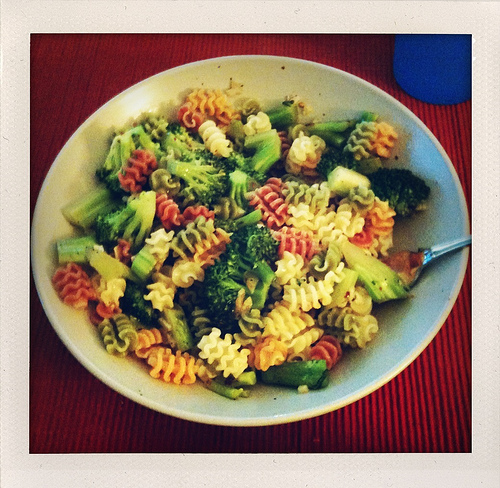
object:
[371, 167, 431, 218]
broccoli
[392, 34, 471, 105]
blue cup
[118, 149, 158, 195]
peice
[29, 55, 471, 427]
peice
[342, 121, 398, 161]
piece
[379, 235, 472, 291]
fork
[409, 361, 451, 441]
motorcycles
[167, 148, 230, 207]
broccoli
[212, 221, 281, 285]
broccoli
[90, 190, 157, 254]
broccoli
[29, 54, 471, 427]
bowl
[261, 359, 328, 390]
broccoli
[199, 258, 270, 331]
broccoli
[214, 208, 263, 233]
broccoli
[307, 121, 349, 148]
broccoli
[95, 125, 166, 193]
broccoli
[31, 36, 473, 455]
table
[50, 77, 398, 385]
noodles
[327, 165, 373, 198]
piece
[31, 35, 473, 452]
placement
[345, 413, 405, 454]
stripes